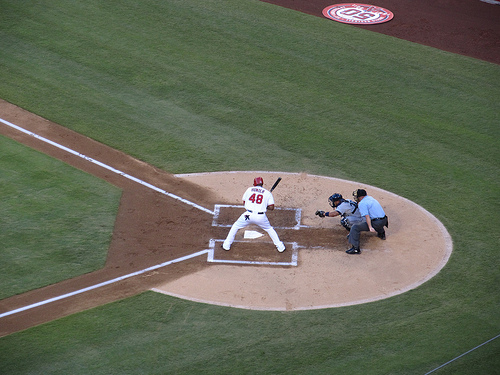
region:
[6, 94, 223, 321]
Part of a baseball diamond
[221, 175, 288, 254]
A baseball player up to bat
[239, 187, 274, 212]
Baseball shirt with number 48 on the back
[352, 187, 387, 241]
A baseball umpire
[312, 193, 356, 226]
A baseball catcher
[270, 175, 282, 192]
A black baseball bat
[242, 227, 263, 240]
Home plate on a baseball field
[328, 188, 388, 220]
Two men wearing blue shirts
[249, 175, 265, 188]
A man wearing a red helmet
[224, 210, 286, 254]
A man wearing white pants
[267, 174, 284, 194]
The bat in the man's hand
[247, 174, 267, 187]
the helmet on the batter's head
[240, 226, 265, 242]
home plate of the baseball field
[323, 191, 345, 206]
the helmet on the catcher's head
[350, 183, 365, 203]
the mask on the umpire's face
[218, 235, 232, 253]
the batter's left shoe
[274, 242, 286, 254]
the batter's right shoe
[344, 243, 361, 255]
the umpire's left shoe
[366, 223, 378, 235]
the umpire's left hand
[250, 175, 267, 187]
a red baseball helmet on the man's head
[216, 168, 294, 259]
Batter ready to swing.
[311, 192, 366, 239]
Catcher ready to catch the ball.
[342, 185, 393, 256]
Umpire watching the play.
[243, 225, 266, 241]
Home plate on the field.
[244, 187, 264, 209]
Number of the player on the jersey.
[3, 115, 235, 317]
White lines on the field going to the bases.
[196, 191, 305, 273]
Batting area on the field.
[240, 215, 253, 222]
Glove in the player's pocket.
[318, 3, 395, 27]
Large circular area with the number 50 on it.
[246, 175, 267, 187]
Red helmet on the player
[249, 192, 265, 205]
The number of the baseball player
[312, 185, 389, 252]
The catcher and the umpire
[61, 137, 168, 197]
The baseline to first base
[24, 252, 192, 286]
The baseline between home plate and third base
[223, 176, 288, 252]
The batter at home plate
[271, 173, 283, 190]
The baseball bat is black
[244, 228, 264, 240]
Home plate beneath the batter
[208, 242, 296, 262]
The left batter's box at home plate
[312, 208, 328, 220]
The glove of the catcher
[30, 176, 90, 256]
Green grass in the infield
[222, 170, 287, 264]
a baseball player batting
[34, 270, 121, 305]
the white line of a baseball diamond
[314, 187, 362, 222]
the catcher of a baseball game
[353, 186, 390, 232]
the umpire of a baseball game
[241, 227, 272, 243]
the home plate of a baseball diamondd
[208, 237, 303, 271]
the batters box of a baseball diamond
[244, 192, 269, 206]
a red number on the back of a shirt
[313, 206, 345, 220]
the arm of a person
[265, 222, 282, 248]
the leg of a person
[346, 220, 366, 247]
the leg of a person